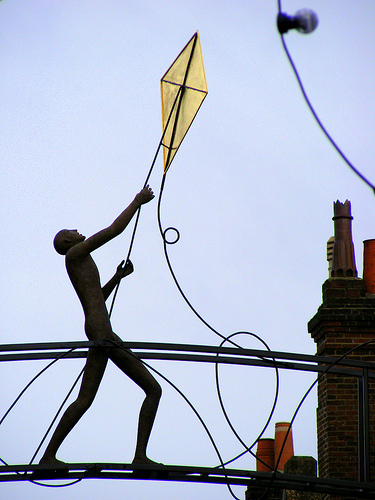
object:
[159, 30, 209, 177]
kite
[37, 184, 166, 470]
statue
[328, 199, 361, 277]
chimneys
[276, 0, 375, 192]
string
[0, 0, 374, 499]
sky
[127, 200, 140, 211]
right wrist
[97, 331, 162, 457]
legs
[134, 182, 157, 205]
hand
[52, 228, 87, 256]
head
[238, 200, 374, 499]
building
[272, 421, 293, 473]
smoke towers